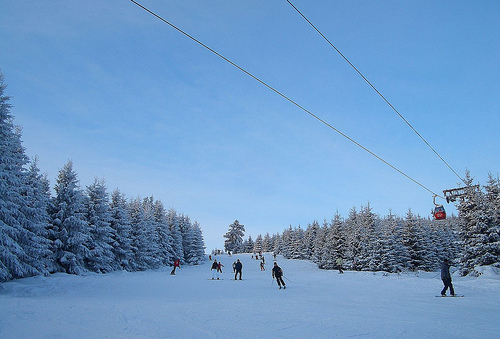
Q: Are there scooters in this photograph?
A: No, there are no scooters.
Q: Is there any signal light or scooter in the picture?
A: No, there are no scooters or traffic lights.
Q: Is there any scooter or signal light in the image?
A: No, there are no scooters or traffic lights.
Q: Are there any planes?
A: No, there are no planes.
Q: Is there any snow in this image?
A: Yes, there is snow.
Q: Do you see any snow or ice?
A: Yes, there is snow.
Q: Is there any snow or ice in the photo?
A: Yes, there is snow.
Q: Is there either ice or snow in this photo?
A: Yes, there is snow.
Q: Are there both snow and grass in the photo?
A: No, there is snow but no grass.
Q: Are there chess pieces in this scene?
A: No, there are no chess pieces.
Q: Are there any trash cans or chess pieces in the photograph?
A: No, there are no chess pieces or trash cans.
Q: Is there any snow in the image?
A: Yes, there is snow.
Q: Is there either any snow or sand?
A: Yes, there is snow.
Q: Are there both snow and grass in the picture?
A: No, there is snow but no grass.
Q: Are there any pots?
A: No, there are no pots.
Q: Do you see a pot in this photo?
A: No, there are no pots.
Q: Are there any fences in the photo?
A: No, there are no fences.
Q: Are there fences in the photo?
A: No, there are no fences.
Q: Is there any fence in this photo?
A: No, there are no fences.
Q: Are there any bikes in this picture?
A: No, there are no bikes.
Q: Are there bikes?
A: No, there are no bikes.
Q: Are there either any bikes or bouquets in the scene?
A: No, there are no bikes or bouquets.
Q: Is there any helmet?
A: No, there are no helmets.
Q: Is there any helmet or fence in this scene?
A: No, there are no helmets or fences.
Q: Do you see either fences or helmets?
A: No, there are no helmets or fences.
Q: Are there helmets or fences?
A: No, there are no helmets or fences.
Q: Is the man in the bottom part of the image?
A: Yes, the man is in the bottom of the image.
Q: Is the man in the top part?
A: No, the man is in the bottom of the image.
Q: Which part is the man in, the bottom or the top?
A: The man is in the bottom of the image.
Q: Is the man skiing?
A: Yes, the man is skiing.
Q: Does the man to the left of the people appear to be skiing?
A: Yes, the man is skiing.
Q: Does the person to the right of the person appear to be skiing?
A: Yes, the man is skiing.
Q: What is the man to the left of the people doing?
A: The man is skiing.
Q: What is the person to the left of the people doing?
A: The man is skiing.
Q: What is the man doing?
A: The man is skiing.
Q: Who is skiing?
A: The man is skiing.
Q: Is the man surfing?
A: No, the man is skiing.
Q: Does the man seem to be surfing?
A: No, the man is skiing.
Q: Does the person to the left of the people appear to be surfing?
A: No, the man is skiing.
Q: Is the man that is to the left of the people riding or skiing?
A: The man is skiing.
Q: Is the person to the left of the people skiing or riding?
A: The man is skiing.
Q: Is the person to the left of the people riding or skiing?
A: The man is skiing.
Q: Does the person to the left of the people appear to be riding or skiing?
A: The man is skiing.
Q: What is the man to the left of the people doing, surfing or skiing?
A: The man is skiing.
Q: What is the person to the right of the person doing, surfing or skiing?
A: The man is skiing.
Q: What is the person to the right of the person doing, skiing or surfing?
A: The man is skiing.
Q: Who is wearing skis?
A: The man is wearing skis.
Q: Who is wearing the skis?
A: The man is wearing skis.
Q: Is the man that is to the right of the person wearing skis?
A: Yes, the man is wearing skis.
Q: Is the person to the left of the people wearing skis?
A: Yes, the man is wearing skis.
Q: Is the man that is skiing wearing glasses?
A: No, the man is wearing skis.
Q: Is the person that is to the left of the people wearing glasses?
A: No, the man is wearing skis.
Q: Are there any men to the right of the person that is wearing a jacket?
A: Yes, there is a man to the right of the person.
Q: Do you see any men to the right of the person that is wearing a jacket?
A: Yes, there is a man to the right of the person.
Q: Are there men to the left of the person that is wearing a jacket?
A: No, the man is to the right of the person.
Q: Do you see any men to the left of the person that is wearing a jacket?
A: No, the man is to the right of the person.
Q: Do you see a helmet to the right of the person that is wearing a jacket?
A: No, there is a man to the right of the person.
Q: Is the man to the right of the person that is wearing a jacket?
A: Yes, the man is to the right of the person.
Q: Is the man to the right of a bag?
A: No, the man is to the right of the person.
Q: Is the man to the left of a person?
A: No, the man is to the right of a person.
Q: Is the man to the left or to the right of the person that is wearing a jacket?
A: The man is to the right of the person.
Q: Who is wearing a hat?
A: The man is wearing a hat.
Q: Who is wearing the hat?
A: The man is wearing a hat.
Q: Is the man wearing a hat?
A: Yes, the man is wearing a hat.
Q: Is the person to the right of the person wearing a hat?
A: Yes, the man is wearing a hat.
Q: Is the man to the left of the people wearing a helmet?
A: No, the man is wearing a hat.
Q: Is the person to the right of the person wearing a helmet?
A: No, the man is wearing a hat.